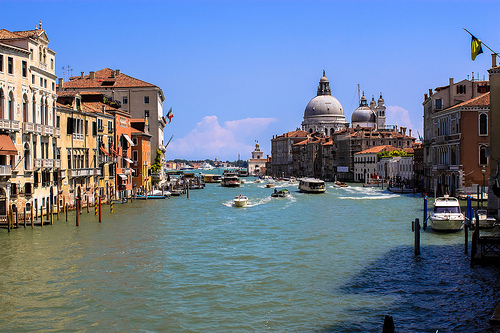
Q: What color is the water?
A: Green.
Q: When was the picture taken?
A: In the day time.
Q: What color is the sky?
A: Blue.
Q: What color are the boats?
A: White.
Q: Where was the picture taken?
A: On a waterway.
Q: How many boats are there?
A: 5.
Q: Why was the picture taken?
A: To show the waterway.